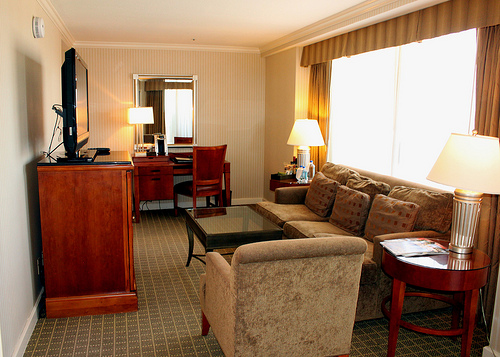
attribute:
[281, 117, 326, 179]
lamp — table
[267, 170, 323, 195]
table — wooden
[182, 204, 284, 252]
coffee table — glass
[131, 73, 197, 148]
mirror — hanging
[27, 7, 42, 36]
smoke alarm — white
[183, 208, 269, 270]
trim — black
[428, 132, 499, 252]
lamp — table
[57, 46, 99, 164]
tv — black, flat screen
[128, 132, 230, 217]
desk — wooden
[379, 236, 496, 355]
table — brown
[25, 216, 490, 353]
carpet — plaid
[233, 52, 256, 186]
wallpaper — striped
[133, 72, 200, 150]
mirror — silver , framed 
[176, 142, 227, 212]
chair — wooden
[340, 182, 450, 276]
magazines — small , a pile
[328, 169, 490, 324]
table — end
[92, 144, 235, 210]
table — wooden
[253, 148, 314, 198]
objects — small